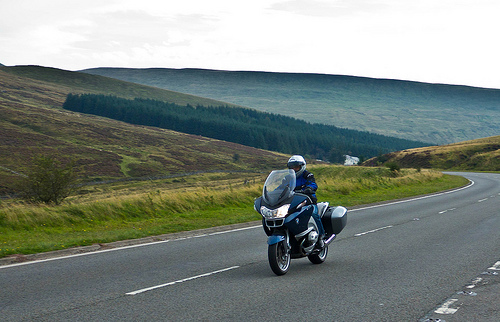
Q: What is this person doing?
A: Riding a motorcycle.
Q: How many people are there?
A: One.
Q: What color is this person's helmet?
A: White.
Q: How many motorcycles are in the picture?
A: One.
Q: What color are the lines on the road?
A: White.